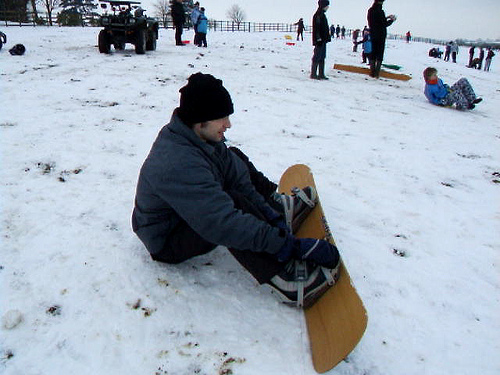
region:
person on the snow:
[133, 71, 335, 308]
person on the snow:
[367, 0, 389, 74]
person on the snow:
[357, 28, 369, 65]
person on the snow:
[422, 65, 477, 108]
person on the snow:
[195, 3, 209, 48]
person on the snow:
[168, 0, 182, 43]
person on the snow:
[187, 1, 200, 28]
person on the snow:
[289, 15, 305, 41]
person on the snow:
[446, 41, 459, 62]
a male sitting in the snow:
[129, 70, 343, 307]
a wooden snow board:
[278, 165, 372, 373]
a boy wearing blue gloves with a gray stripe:
[131, 72, 341, 306]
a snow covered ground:
[0, 27, 495, 372]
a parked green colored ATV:
[97, 5, 157, 56]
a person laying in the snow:
[422, 67, 482, 112]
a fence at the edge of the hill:
[6, 13, 495, 48]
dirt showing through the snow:
[132, 277, 248, 374]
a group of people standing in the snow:
[443, 39, 496, 72]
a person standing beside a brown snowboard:
[333, 0, 414, 82]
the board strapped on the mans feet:
[275, 160, 382, 373]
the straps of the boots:
[290, 259, 336, 308]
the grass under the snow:
[68, 272, 250, 373]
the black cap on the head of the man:
[180, 70, 232, 120]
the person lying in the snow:
[420, 62, 481, 114]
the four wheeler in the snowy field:
[99, 0, 161, 59]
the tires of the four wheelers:
[99, 25, 157, 59]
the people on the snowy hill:
[308, 2, 422, 98]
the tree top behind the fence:
[223, 2, 248, 19]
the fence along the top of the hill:
[209, 21, 293, 34]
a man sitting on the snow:
[121, 57, 319, 319]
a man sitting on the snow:
[108, 50, 352, 321]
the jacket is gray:
[117, 124, 257, 264]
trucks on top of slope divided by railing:
[7, 0, 162, 55]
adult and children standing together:
[160, 0, 215, 45]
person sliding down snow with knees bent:
[415, 65, 480, 110]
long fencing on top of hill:
[0, 5, 445, 45]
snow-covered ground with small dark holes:
[12, 31, 492, 351]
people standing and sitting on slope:
[120, 5, 495, 370]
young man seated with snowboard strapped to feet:
[128, 66, 368, 371]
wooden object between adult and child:
[325, 0, 411, 85]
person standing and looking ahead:
[300, 0, 330, 80]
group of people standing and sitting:
[420, 37, 495, 72]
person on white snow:
[419, 62, 482, 113]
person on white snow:
[310, 0, 331, 82]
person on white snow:
[366, 0, 398, 80]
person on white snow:
[483, 44, 495, 71]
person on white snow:
[468, 41, 477, 61]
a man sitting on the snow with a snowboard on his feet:
[130, 69, 340, 311]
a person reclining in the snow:
[422, 66, 483, 112]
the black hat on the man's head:
[179, 72, 234, 123]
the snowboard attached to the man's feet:
[279, 163, 367, 374]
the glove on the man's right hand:
[277, 231, 339, 268]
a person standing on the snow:
[309, 0, 331, 81]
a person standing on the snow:
[367, 0, 397, 80]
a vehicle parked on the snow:
[97, 6, 160, 56]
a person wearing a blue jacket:
[193, 6, 208, 46]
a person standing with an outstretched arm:
[292, 16, 306, 41]